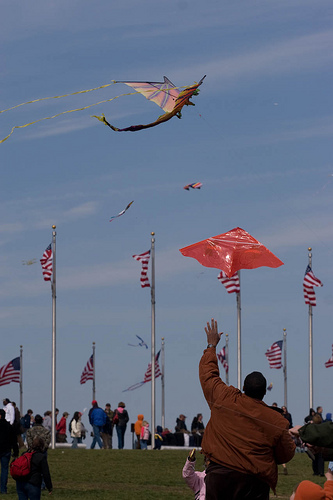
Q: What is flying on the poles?
A: American flags.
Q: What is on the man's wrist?
A: A watch.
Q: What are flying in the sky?
A: Kites.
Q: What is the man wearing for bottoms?
A: Pants.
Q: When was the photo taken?
A: During the daytime.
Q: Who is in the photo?
A: Some people.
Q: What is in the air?
A: A kite.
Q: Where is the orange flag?
A: Above the man.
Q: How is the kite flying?
A: In the air.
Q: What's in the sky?
A: A kite.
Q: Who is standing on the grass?
A: The people.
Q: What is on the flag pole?
A: The American flag.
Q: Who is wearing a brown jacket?
A: A man.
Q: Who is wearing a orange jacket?
A: Kid under flag pole.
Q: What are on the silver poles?
A: Numerous flags.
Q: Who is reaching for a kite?
A: Man with brown jacket.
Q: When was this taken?
A: During the day.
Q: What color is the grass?
A: Green.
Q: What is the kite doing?
A: Flying.